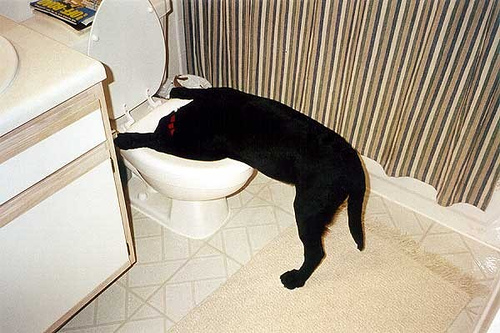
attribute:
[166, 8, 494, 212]
curtain — STRIPED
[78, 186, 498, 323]
floor — TILES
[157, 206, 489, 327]
mat — BROWN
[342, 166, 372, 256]
tail — DOWN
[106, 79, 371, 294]
dog — black, furry, drinking, shiney, small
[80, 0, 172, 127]
lid — UP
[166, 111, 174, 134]
collar — RED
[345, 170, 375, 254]
tail — down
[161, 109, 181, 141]
collar — red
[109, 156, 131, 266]
hinges — metal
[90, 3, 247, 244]
toilet — white, porcelain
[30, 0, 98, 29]
magazines — blue, yellow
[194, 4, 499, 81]
curtain — striped, wavy, tan, black, brown, hanging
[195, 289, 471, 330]
rug — tan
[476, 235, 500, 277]
floor — shiney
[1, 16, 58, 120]
sink — white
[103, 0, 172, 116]
lid — up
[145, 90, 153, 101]
screws — silver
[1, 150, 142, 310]
cabinet — wooden, white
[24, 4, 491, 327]
bathroom — small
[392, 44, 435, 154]
stripes — verticle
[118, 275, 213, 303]
floor — clean